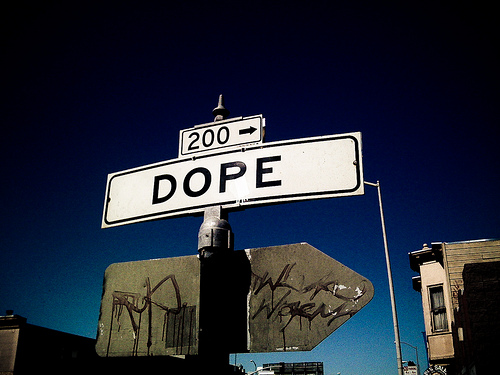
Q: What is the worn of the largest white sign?
A: Dope.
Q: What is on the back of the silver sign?
A: Graffiti.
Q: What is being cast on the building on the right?
A: A shadow.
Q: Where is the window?
A: Building on the right.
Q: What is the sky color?
A: Blue.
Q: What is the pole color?
A: Gray.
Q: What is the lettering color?
A: Black.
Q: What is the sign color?
A: White.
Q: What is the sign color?
A: White.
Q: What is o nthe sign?
A: Graffiti.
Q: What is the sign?
A: One way street.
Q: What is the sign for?
A: Street.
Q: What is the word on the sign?
A: Dope.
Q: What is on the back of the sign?
A: Black writing.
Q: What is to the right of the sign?
A: A building.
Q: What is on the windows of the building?
A: Curtains.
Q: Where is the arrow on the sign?
A: Next to the number 200.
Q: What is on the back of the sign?
A: Graffiti.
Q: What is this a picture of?
A: Sign.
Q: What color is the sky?
A: Blue.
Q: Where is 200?
A: Right.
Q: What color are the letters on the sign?
A: Black.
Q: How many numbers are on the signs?
A: One.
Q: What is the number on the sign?
A: 200.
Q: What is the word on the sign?
A: Dope.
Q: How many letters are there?
A: Four.